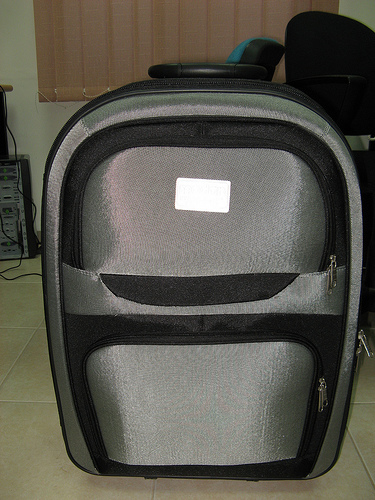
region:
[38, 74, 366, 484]
silver and black luggage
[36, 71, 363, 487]
silver and black suitcase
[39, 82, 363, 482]
silver and black luggage with metal zipper pulls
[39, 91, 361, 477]
silver and black luggage with a white sticker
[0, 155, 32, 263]
the rear view of a desktop computer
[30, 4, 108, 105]
closed tan fabric blinds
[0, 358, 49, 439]
neutral colored floor tile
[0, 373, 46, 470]
clean tile flooring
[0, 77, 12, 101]
the corner of a desk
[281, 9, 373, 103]
back of a black chair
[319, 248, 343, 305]
zipper on upper pocket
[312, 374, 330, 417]
zipper on lower pocket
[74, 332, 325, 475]
lower pocket of bag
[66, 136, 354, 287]
upper pocket of bag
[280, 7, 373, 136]
back of black chair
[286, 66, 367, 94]
armrest of black chair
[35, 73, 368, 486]
Silver and black bag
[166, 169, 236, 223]
White tag on bag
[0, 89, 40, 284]
Electronic black cable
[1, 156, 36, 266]
black and gray electronic equipment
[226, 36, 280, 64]
a blue chair cushion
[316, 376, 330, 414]
a pair of zipper pulls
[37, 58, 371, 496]
a black and grey piece of luggage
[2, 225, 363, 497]
a white tile floor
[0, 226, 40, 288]
a black electrical cord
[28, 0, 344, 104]
some panels of curtains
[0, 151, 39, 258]
a piece of computer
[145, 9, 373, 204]
a pair of office chairs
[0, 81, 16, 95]
the edge of a table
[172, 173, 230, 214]
a square white patch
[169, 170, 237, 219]
White sticker on the suitcase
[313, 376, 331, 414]
Two silver zippers on the suitcase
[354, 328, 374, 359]
One silver zipper on the suitcase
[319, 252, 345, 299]
Two silver zippers on the suitcase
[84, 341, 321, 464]
Silver patch on suitcase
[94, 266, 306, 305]
Rounded black patch on suitcase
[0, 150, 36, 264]
Silver and black piece of machinery in the background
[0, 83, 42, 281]
Long black electrical cord falling off the table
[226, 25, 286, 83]
Top of a blue and black office chair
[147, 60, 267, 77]
Black plastic suitcase handle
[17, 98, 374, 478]
Suitcase is grey and black color.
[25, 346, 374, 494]
Suitcase is in floor.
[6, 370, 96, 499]
Floor is cream color.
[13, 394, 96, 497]
Floor is made of tiles.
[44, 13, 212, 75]
Curtain is brown color.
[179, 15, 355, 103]
Two chair is behind the suitcase.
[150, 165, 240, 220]
Badge is silver color.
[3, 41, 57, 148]
wall is white color.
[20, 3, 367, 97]
Window is closed.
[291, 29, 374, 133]
Chair is black color.